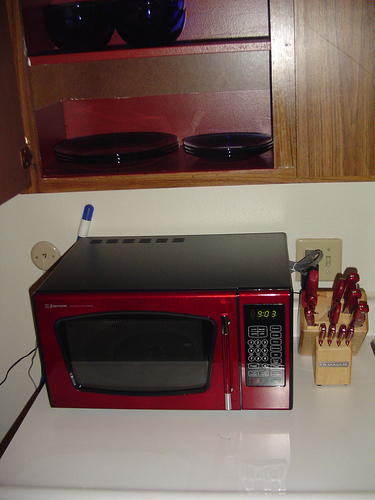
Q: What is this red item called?
A: Microwave.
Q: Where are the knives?
A: In the wooden knife holder.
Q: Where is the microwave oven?
A: On the counter.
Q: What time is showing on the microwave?
A: 9:03.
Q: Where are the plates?
A: Stacked in the cabinet.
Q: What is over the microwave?
A: A wooden shelf.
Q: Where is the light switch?
A: Behind the knives.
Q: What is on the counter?
A: A microwave oven and knives.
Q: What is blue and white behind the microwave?
A: A handle.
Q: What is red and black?
A: A microwave oven.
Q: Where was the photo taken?
A: In a kitchen.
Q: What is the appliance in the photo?
A: A microwave oven.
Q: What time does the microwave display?
A: 9:03.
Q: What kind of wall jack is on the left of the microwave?
A: A phone jack.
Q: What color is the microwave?
A: Black and red.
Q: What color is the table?
A: White.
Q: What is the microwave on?
A: The table.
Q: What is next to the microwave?
A: Knives.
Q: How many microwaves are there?
A: One.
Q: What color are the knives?
A: Red.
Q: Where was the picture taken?
A: In a kitchen.